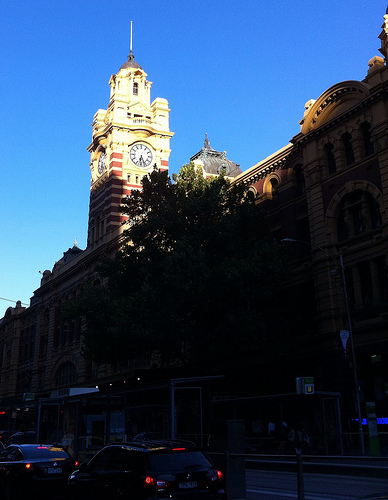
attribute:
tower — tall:
[90, 11, 172, 251]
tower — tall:
[86, 20, 175, 245]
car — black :
[64, 433, 231, 498]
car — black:
[70, 439, 227, 498]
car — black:
[1, 443, 75, 498]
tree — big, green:
[131, 175, 259, 377]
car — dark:
[95, 425, 266, 498]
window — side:
[94, 448, 142, 472]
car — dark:
[10, 426, 84, 495]